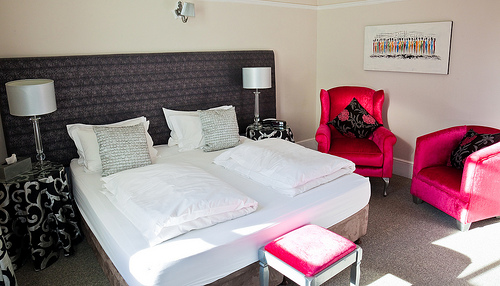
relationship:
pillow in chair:
[337, 103, 373, 134] [316, 88, 394, 176]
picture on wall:
[364, 27, 450, 71] [317, 8, 499, 172]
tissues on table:
[8, 160, 25, 174] [7, 164, 77, 253]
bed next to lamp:
[76, 142, 361, 266] [239, 68, 275, 88]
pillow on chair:
[452, 132, 494, 168] [414, 129, 499, 219]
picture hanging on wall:
[364, 27, 450, 71] [317, 8, 499, 172]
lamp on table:
[239, 68, 275, 88] [244, 124, 291, 146]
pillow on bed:
[92, 124, 152, 169] [76, 142, 361, 266]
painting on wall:
[364, 27, 450, 71] [317, 8, 499, 172]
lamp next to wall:
[9, 81, 58, 110] [4, 2, 316, 150]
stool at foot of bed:
[258, 224, 373, 280] [76, 142, 361, 266]